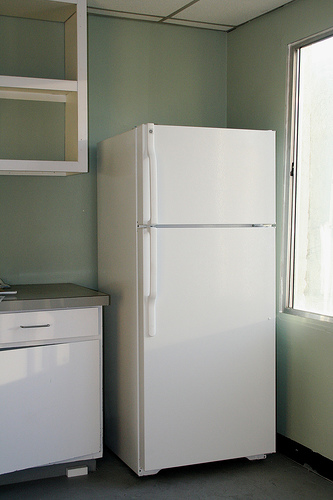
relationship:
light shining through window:
[1, 149, 280, 380] [290, 36, 332, 314]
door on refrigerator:
[138, 226, 277, 471] [93, 120, 284, 474]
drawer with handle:
[0, 306, 99, 344] [18, 322, 50, 328]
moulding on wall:
[273, 430, 330, 476] [276, 314, 332, 462]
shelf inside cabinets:
[0, 71, 76, 100] [0, 0, 89, 179]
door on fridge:
[138, 229, 196, 292] [123, 126, 260, 379]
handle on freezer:
[143, 145, 163, 215] [92, 122, 284, 232]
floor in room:
[171, 464, 292, 494] [15, 24, 319, 351]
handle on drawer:
[19, 323, 49, 328] [2, 300, 115, 357]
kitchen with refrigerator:
[2, 3, 331, 498] [75, 86, 320, 499]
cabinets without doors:
[0, 0, 91, 179] [6, 13, 81, 164]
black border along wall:
[283, 434, 326, 472] [303, 338, 326, 493]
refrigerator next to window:
[71, 107, 291, 475] [283, 36, 322, 330]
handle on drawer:
[19, 323, 50, 329] [0, 304, 104, 346]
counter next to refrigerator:
[1, 277, 111, 303] [103, 97, 288, 491]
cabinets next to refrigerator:
[0, 0, 89, 179] [93, 120, 284, 474]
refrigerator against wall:
[96, 122, 277, 478] [97, 18, 251, 135]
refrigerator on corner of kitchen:
[96, 122, 277, 478] [2, 3, 331, 498]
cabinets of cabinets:
[0, 0, 89, 179] [0, 0, 89, 179]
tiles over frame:
[211, 467, 291, 498] [98, 0, 279, 68]